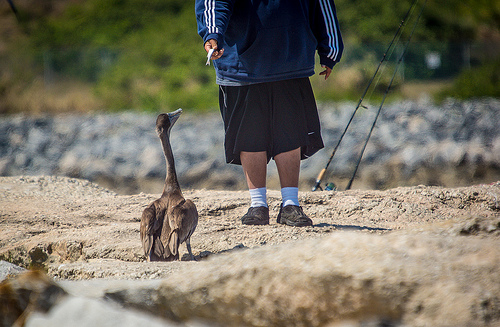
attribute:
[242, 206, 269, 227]
shoe — brown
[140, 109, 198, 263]
duck — looking up, brown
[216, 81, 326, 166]
shorts — black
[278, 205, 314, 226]
shoe — brown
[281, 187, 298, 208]
sock — white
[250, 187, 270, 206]
sock — white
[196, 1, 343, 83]
sweatshirt — blue, white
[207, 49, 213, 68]
fish — small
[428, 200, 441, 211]
dirt — brown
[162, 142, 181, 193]
neck — long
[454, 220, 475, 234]
rock — bid